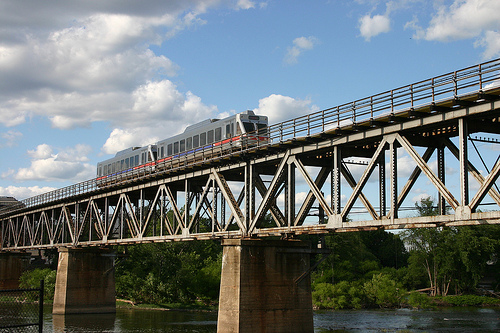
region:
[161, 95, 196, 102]
part of a cloiud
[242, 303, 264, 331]
part of a pillar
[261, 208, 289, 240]
part of a bridge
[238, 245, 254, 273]
part of a pillar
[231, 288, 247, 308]
edge of a pillar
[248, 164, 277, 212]
part of a metal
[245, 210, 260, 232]
part of a metal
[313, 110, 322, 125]
part of a rail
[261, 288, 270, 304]
part of a wall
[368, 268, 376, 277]
part of a forest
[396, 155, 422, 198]
bottom of a bridge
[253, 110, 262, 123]
part of a train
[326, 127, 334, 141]
part of a bridge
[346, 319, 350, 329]
part of a river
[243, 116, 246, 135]
edge of a train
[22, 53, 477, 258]
a train travels over a bridge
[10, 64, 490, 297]
train travels to the right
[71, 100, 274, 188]
train is gray with blue and orange stripes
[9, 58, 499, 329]
a bridge over the water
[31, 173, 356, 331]
columns of concrete supporting a bridge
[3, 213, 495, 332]
water under a bridge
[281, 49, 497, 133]
a metal fence on side the bridge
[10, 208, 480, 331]
trees in the shore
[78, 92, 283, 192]
train has two cars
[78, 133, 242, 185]
blue and orange stripes on side train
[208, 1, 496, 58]
white clouds in sky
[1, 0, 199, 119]
gray and white clouds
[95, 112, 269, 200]
two tain cars on rail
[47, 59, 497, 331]
train travelling over bridge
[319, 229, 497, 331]
trees on water bank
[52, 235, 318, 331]
stone pillars under bridge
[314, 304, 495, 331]
light reflection on water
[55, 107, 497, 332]
train bridge over water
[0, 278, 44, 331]
pole on side of fence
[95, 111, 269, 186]
silver train with red stripes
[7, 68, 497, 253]
a metal train bridge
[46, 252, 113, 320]
a concrete pillar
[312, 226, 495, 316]
a group of leafy green trees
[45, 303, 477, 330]
water under the bridge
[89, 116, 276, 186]
a train on the bridge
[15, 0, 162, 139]
a cloudy sky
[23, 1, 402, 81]
a blue and white sky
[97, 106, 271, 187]
a silver and red train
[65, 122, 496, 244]
steel beam on a bridge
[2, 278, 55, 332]
a black mash fence